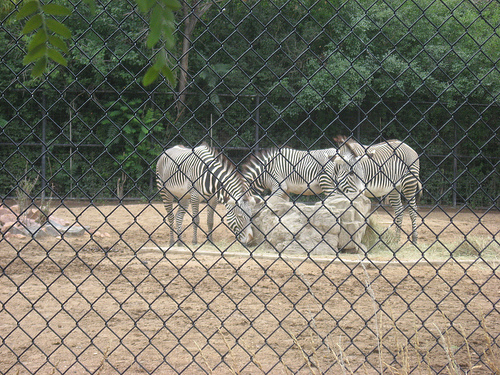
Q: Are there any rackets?
A: No, there are no rackets.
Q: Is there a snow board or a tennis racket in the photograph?
A: No, there are no rackets or snowboards.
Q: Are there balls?
A: No, there are no balls.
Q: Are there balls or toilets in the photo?
A: No, there are no balls or toilets.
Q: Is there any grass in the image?
A: Yes, there is grass.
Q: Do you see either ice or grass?
A: Yes, there is grass.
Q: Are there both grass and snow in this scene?
A: No, there is grass but no snow.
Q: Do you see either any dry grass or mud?
A: Yes, there is dry grass.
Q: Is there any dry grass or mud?
A: Yes, there is dry grass.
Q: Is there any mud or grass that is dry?
A: Yes, the grass is dry.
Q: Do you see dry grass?
A: Yes, there is dry grass.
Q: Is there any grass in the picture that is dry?
A: Yes, there is grass that is dry.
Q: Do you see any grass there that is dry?
A: Yes, there is grass that is dry.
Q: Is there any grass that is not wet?
A: Yes, there is dry grass.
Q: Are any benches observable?
A: No, there are no benches.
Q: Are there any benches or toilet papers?
A: No, there are no benches or toilet papers.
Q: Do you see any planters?
A: No, there are no planters.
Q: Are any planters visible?
A: No, there are no planters.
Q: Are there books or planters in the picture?
A: No, there are no planters or books.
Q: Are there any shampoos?
A: No, there are no shampoos.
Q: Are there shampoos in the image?
A: No, there are no shampoos.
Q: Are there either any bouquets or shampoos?
A: No, there are no shampoos or bouquets.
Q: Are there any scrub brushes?
A: No, there are no scrub brushes.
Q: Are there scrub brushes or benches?
A: No, there are no scrub brushes or benches.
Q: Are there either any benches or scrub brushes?
A: No, there are no scrub brushes or benches.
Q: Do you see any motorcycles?
A: No, there are no motorcycles.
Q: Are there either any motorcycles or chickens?
A: No, there are no motorcycles or chickens.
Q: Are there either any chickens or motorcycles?
A: No, there are no motorcycles or chickens.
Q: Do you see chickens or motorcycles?
A: No, there are no motorcycles or chickens.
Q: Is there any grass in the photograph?
A: Yes, there is grass.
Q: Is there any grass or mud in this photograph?
A: Yes, there is grass.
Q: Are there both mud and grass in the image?
A: No, there is grass but no mud.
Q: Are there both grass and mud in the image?
A: No, there is grass but no mud.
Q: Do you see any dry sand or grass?
A: Yes, there is dry grass.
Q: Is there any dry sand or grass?
A: Yes, there is dry grass.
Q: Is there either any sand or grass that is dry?
A: Yes, the grass is dry.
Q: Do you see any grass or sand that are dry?
A: Yes, the grass is dry.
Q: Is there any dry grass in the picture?
A: Yes, there is dry grass.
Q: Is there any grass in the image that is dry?
A: Yes, there is grass that is dry.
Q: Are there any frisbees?
A: No, there are no frisbees.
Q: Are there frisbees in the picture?
A: No, there are no frisbees.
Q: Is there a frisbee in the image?
A: No, there are no frisbees.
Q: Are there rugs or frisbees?
A: No, there are no frisbees or rugs.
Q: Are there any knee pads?
A: No, there are no knee pads.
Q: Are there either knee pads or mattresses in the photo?
A: No, there are no knee pads or mattresses.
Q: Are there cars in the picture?
A: No, there are no cars.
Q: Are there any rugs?
A: No, there are no rugs.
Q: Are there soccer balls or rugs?
A: No, there are no rugs or soccer balls.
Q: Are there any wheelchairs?
A: No, there are no wheelchairs.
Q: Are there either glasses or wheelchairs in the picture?
A: No, there are no wheelchairs or glasses.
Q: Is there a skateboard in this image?
A: No, there are no skateboards.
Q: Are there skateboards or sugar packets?
A: No, there are no skateboards or sugar packets.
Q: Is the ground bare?
A: Yes, the ground is bare.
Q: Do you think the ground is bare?
A: Yes, the ground is bare.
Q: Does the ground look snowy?
A: No, the ground is bare.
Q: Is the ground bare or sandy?
A: The ground is bare.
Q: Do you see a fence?
A: Yes, there is a fence.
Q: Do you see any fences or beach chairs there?
A: Yes, there is a fence.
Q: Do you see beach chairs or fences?
A: Yes, there is a fence.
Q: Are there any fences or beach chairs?
A: Yes, there is a fence.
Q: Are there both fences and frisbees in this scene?
A: No, there is a fence but no frisbees.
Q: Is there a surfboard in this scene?
A: No, there are no surfboards.